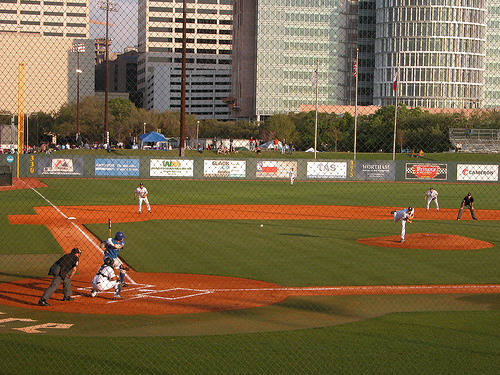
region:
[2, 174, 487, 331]
a base ball field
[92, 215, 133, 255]
a man holding a baseball bat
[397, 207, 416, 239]
a man throwing a baseball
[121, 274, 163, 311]
home plate on a baseball field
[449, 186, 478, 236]
a man bent down with hands on his knees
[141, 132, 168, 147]
a blue canopy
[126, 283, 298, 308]
white chalk lines on a baseball field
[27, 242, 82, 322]
a man wearing a black vest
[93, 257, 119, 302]
a man knelt down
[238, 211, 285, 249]
a base ball in the air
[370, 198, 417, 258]
the pitcher threw the ball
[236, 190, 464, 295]
the pitcher threw the ball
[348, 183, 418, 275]
the pitcher threw the ball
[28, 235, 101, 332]
the umpire's shirt is black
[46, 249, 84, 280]
the umpire's shirt is black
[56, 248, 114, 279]
the umpire's shirt is black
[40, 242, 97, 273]
the umpire's shirt is black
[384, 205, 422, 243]
A pitcher throwing a pitch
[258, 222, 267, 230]
The baseball travelling through the air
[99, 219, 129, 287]
A batter standing at the plate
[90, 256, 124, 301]
The catcher crouching behind the plate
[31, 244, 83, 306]
The umpire crouching behind the catcher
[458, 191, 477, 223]
The second base coach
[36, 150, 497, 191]
Signs on the outfield wall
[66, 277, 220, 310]
White lines around the batter's box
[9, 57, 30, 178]
A tall yellow foul ball pole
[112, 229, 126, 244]
A blue batting helmet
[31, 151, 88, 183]
sign on baseball banner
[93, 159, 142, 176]
sign on baseball banner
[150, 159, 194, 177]
sign on baseball banner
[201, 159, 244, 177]
sign on baseball banner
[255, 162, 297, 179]
sign on baseball banner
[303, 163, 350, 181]
sign on baseball banner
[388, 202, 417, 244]
baseball pitcher throwing ball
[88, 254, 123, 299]
baseball catcher getting ready for a catch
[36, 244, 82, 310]
umpire watching the game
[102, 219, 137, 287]
batter getting ready to play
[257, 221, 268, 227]
a white baseball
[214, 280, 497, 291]
a long white line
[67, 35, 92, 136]
a long a tall light pole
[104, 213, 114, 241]
a baseball bat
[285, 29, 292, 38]
a window of a building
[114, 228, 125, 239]
a blue baseball helmet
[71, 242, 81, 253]
a black baseball helmet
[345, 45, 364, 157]
a tall flag pole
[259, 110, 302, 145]
a large green tree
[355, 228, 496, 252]
a pitcher's mound